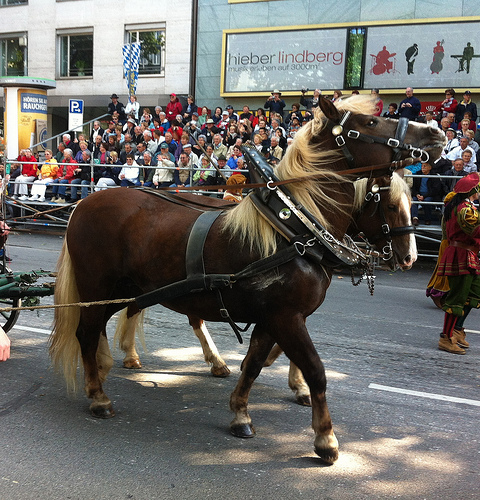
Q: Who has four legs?
A: One horse.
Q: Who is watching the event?
A: Spectators.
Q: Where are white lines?
A: On the street.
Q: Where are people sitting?
A: On bleachers.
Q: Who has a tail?
A: The horses.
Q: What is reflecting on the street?
A: Sunlight.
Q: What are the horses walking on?
A: The street.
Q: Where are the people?
A: In the bleachers.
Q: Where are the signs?
A: Above the people.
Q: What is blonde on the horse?
A: Mane and tail.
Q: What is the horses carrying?
A: A cart.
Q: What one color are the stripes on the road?
A: White.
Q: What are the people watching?
A: A parade.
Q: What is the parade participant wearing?
A: A costume.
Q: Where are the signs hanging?
A: On a wall.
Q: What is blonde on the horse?
A: Mane and tail.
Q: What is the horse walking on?
A: A street.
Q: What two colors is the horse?
A: Brown and blonde.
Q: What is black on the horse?
A: The bridle.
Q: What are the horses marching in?
A: A parade.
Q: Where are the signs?
A: Behind the people.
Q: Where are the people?
A: On the side of the street.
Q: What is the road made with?
A: Concrete.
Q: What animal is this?
A: A horse.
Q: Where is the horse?
A: On the street.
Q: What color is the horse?
A: Brown.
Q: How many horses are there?
A: One.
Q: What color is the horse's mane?
A: Blonde.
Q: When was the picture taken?
A: During the parade.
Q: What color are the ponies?
A: Brown.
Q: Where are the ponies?
A: In the street.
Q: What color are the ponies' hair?
A: Blonde.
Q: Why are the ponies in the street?
A: For the parade.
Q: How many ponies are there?
A: Two.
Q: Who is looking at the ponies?
A: The crowd.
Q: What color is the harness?
A: Black.